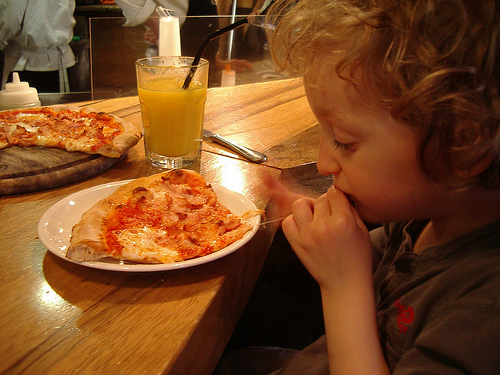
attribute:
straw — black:
[178, 25, 258, 89]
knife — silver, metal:
[189, 112, 275, 178]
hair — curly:
[278, 10, 494, 176]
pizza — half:
[58, 176, 245, 262]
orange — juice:
[133, 81, 203, 160]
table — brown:
[4, 271, 204, 373]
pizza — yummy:
[69, 166, 252, 264]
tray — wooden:
[0, 130, 120, 192]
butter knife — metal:
[197, 111, 272, 183]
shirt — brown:
[262, 224, 499, 372]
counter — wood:
[3, 77, 308, 374]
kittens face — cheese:
[63, 162, 254, 273]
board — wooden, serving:
[1, 145, 126, 196]